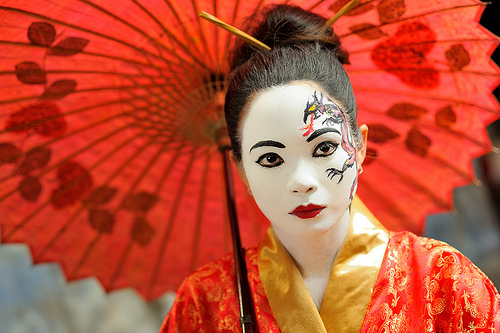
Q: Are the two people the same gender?
A: Yes, all the people are female.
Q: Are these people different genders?
A: No, all the people are female.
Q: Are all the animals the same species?
A: Yes, all the animals are dragons.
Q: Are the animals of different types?
A: No, all the animals are dragons.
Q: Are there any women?
A: Yes, there is a woman.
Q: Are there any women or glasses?
A: Yes, there is a woman.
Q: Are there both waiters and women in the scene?
A: No, there is a woman but no waiters.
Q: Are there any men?
A: No, there are no men.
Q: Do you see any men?
A: No, there are no men.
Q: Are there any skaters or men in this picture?
A: No, there are no men or skaters.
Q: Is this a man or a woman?
A: This is a woman.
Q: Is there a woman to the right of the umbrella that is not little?
A: Yes, there is a woman to the right of the umbrella.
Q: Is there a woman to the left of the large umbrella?
A: No, the woman is to the right of the umbrella.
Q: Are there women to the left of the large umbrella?
A: No, the woman is to the right of the umbrella.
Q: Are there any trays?
A: No, there are no trays.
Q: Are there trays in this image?
A: No, there are no trays.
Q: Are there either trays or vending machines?
A: No, there are no trays or vending machines.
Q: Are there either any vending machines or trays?
A: No, there are no trays or vending machines.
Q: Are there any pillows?
A: No, there are no pillows.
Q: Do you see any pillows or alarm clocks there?
A: No, there are no pillows or alarm clocks.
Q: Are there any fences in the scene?
A: No, there are no fences.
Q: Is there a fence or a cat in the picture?
A: No, there are no fences or cats.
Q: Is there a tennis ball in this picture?
A: No, there are no tennis balls.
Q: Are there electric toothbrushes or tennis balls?
A: No, there are no tennis balls or electric toothbrushes.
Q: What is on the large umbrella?
A: The flower is on the umbrella.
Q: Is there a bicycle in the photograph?
A: No, there are no bicycles.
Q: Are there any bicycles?
A: No, there are no bicycles.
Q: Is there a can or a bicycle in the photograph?
A: No, there are no bicycles or cans.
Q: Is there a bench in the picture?
A: No, there are no benches.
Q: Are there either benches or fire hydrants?
A: No, there are no benches or fire hydrants.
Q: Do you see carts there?
A: No, there are no carts.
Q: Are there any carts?
A: No, there are no carts.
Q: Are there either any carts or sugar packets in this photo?
A: No, there are no carts or sugar packets.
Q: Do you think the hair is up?
A: Yes, the hair is up.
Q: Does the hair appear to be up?
A: Yes, the hair is up.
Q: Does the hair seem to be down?
A: No, the hair is up.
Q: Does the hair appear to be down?
A: No, the hair is up.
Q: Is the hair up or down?
A: The hair is up.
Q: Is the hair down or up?
A: The hair is up.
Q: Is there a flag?
A: No, there are no flags.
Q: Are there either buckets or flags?
A: No, there are no flags or buckets.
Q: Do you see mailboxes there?
A: No, there are no mailboxes.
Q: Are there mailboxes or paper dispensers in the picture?
A: No, there are no mailboxes or paper dispensers.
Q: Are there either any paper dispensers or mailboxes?
A: No, there are no mailboxes or paper dispensers.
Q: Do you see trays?
A: No, there are no trays.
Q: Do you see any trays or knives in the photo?
A: No, there are no trays or knives.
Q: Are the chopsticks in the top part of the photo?
A: Yes, the chopsticks are in the top of the image.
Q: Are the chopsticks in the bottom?
A: No, the chopsticks are in the top of the image.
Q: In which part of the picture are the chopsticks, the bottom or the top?
A: The chopsticks are in the top of the image.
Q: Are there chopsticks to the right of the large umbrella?
A: Yes, there are chopsticks to the right of the umbrella.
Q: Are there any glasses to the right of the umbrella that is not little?
A: No, there are chopsticks to the right of the umbrella.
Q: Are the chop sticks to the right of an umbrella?
A: Yes, the chop sticks are to the right of an umbrella.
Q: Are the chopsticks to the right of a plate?
A: No, the chopsticks are to the right of an umbrella.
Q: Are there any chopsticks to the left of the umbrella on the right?
A: Yes, there are chopsticks to the left of the umbrella.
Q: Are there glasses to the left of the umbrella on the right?
A: No, there are chopsticks to the left of the umbrella.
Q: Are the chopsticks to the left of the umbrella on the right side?
A: Yes, the chopsticks are to the left of the umbrella.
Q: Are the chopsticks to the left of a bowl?
A: No, the chopsticks are to the left of the umbrella.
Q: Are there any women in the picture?
A: Yes, there is a woman.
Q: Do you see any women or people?
A: Yes, there is a woman.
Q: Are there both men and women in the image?
A: No, there is a woman but no men.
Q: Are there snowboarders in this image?
A: No, there are no snowboarders.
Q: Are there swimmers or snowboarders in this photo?
A: No, there are no snowboarders or swimmers.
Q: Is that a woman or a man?
A: That is a woman.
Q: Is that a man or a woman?
A: That is a woman.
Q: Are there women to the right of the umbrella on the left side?
A: Yes, there is a woman to the right of the umbrella.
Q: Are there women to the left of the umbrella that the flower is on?
A: No, the woman is to the right of the umbrella.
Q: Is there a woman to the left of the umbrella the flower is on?
A: No, the woman is to the right of the umbrella.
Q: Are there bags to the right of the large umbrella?
A: No, there is a woman to the right of the umbrella.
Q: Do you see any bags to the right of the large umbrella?
A: No, there is a woman to the right of the umbrella.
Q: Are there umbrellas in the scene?
A: Yes, there is an umbrella.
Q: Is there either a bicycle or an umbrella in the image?
A: Yes, there is an umbrella.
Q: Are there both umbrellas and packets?
A: No, there is an umbrella but no packets.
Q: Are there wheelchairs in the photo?
A: No, there are no wheelchairs.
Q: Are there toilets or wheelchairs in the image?
A: No, there are no wheelchairs or toilets.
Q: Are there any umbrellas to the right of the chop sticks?
A: Yes, there is an umbrella to the right of the chop sticks.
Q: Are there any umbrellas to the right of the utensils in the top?
A: Yes, there is an umbrella to the right of the chop sticks.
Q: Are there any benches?
A: No, there are no benches.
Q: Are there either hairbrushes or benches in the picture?
A: No, there are no benches or hairbrushes.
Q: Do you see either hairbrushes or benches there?
A: No, there are no benches or hairbrushes.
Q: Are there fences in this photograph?
A: No, there are no fences.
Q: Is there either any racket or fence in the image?
A: No, there are no fences or rackets.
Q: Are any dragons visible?
A: Yes, there is a dragon.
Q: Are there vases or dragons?
A: Yes, there is a dragon.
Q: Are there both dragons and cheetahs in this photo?
A: No, there is a dragon but no cheetahs.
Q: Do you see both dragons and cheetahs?
A: No, there is a dragon but no cheetahs.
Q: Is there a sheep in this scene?
A: No, there is no sheep.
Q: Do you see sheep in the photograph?
A: No, there are no sheep.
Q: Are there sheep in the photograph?
A: No, there are no sheep.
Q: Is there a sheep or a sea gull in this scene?
A: No, there are no sheep or seagulls.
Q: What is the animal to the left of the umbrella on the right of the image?
A: The animal is a dragon.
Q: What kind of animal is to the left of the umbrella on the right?
A: The animal is a dragon.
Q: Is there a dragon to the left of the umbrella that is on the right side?
A: Yes, there is a dragon to the left of the umbrella.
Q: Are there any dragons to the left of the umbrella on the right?
A: Yes, there is a dragon to the left of the umbrella.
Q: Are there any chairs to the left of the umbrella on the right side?
A: No, there is a dragon to the left of the umbrella.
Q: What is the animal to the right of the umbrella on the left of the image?
A: The animal is a dragon.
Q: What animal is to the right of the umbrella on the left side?
A: The animal is a dragon.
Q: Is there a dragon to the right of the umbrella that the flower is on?
A: Yes, there is a dragon to the right of the umbrella.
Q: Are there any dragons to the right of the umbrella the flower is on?
A: Yes, there is a dragon to the right of the umbrella.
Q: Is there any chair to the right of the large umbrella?
A: No, there is a dragon to the right of the umbrella.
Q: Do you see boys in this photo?
A: No, there are no boys.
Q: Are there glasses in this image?
A: No, there are no glasses.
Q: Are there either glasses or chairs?
A: No, there are no glasses or chairs.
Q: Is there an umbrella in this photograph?
A: Yes, there is an umbrella.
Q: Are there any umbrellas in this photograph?
A: Yes, there is an umbrella.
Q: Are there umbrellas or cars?
A: Yes, there is an umbrella.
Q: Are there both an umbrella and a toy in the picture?
A: No, there is an umbrella but no toys.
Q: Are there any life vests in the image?
A: No, there are no life vests.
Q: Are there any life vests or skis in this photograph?
A: No, there are no life vests or skis.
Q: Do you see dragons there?
A: Yes, there is a dragon.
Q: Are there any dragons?
A: Yes, there is a dragon.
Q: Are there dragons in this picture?
A: Yes, there is a dragon.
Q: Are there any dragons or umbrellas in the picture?
A: Yes, there is a dragon.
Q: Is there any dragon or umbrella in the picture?
A: Yes, there is a dragon.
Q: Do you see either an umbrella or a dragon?
A: Yes, there is a dragon.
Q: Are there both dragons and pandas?
A: No, there is a dragon but no pandas.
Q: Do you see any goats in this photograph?
A: No, there are no goats.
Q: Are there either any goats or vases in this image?
A: No, there are no goats or vases.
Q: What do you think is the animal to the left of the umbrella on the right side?
A: The animal is a dragon.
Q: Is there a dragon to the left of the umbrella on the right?
A: Yes, there is a dragon to the left of the umbrella.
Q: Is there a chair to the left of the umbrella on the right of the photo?
A: No, there is a dragon to the left of the umbrella.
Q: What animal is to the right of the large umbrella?
A: The animal is a dragon.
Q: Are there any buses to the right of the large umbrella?
A: No, there is a dragon to the right of the umbrella.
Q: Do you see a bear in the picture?
A: No, there are no bears.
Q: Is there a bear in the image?
A: No, there are no bears.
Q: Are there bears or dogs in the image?
A: No, there are no bears or dogs.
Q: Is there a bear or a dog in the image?
A: No, there are no bears or dogs.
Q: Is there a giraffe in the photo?
A: No, there are no giraffes.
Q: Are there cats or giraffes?
A: No, there are no giraffes or cats.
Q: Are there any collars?
A: Yes, there is a collar.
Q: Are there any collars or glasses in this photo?
A: Yes, there is a collar.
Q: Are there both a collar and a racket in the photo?
A: No, there is a collar but no rackets.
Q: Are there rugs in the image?
A: No, there are no rugs.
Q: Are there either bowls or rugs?
A: No, there are no rugs or bowls.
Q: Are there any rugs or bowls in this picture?
A: No, there are no rugs or bowls.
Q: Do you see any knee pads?
A: No, there are no knee pads.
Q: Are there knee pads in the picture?
A: No, there are no knee pads.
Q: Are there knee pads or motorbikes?
A: No, there are no knee pads or motorbikes.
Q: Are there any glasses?
A: No, there are no glasses.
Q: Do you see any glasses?
A: No, there are no glasses.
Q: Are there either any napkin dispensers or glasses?
A: No, there are no glasses or napkin dispensers.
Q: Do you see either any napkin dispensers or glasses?
A: No, there are no glasses or napkin dispensers.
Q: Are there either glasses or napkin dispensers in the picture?
A: No, there are no glasses or napkin dispensers.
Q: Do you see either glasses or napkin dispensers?
A: No, there are no glasses or napkin dispensers.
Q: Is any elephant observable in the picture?
A: No, there are no elephants.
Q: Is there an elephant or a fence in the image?
A: No, there are no elephants or fences.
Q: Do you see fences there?
A: No, there are no fences.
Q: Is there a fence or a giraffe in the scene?
A: No, there are no fences or giraffes.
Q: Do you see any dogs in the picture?
A: No, there are no dogs.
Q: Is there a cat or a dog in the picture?
A: No, there are no dogs or cats.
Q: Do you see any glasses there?
A: No, there are no glasses.